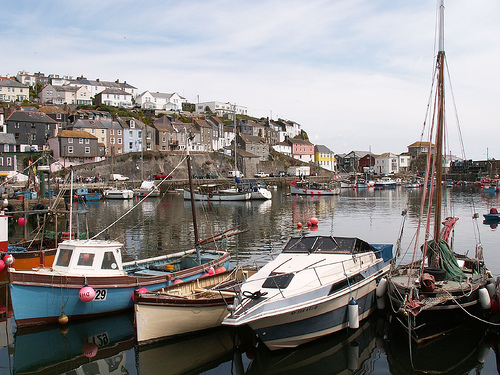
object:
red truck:
[152, 172, 172, 181]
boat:
[133, 181, 160, 196]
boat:
[404, 180, 422, 188]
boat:
[339, 179, 370, 188]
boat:
[290, 177, 341, 194]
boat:
[0, 230, 96, 285]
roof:
[7, 110, 56, 123]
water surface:
[1, 344, 202, 371]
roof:
[407, 141, 435, 148]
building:
[407, 140, 436, 160]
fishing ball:
[307, 217, 318, 225]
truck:
[110, 173, 130, 182]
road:
[41, 165, 330, 183]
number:
[95, 290, 101, 300]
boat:
[7, 238, 230, 328]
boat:
[256, 182, 277, 190]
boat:
[103, 190, 134, 199]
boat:
[395, 177, 407, 185]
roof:
[59, 130, 98, 139]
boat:
[15, 190, 54, 200]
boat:
[387, 251, 496, 345]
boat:
[75, 188, 101, 200]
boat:
[251, 186, 272, 199]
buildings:
[38, 83, 93, 105]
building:
[47, 129, 99, 172]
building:
[314, 144, 335, 172]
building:
[113, 112, 142, 152]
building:
[148, 123, 177, 151]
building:
[194, 119, 213, 151]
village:
[0, 60, 494, 208]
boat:
[221, 236, 395, 351]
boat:
[183, 189, 251, 200]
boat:
[134, 265, 266, 342]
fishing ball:
[297, 222, 302, 227]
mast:
[423, 51, 446, 282]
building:
[286, 137, 315, 163]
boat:
[373, 177, 396, 189]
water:
[198, 200, 275, 227]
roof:
[314, 144, 334, 153]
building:
[0, 108, 58, 153]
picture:
[0, 0, 500, 373]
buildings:
[134, 90, 186, 112]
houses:
[260, 116, 302, 144]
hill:
[1, 74, 337, 186]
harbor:
[4, 159, 498, 373]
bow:
[242, 291, 261, 300]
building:
[0, 78, 30, 102]